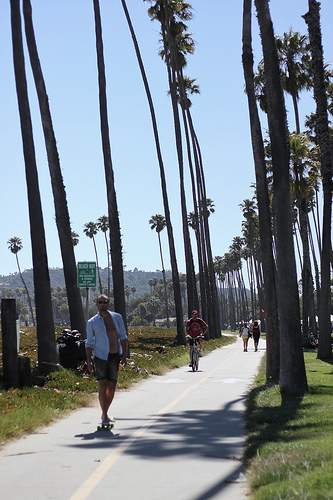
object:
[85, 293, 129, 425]
man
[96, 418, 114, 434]
skateboard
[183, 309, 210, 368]
man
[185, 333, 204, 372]
bike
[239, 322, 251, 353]
woman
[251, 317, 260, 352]
woman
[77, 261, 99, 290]
sign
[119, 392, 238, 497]
road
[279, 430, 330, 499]
grass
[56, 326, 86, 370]
trash can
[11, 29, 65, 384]
tree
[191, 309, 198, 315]
hat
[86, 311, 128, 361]
shirt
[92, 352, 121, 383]
shorts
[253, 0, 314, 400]
tree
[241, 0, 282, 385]
tree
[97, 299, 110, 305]
sunglasses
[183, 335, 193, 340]
handlebar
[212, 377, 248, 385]
arrow